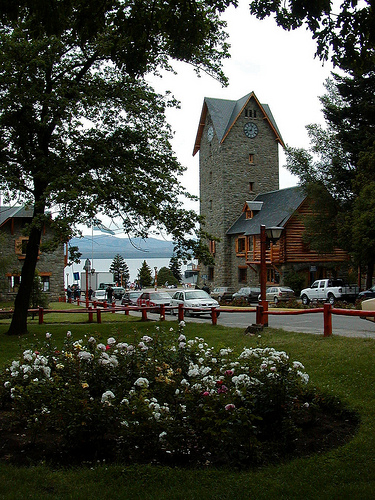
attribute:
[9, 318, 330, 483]
flowers — white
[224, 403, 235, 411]
flowers — multi colored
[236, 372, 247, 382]
flowers — multi colored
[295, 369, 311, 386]
flowers — multi colored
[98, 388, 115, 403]
flowers — multi colored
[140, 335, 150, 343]
flowers — multi colored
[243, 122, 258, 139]
clock — large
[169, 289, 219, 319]
car — parked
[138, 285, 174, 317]
car — parked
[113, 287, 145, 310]
car — parked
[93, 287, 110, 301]
car — parked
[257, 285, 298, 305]
car — parked